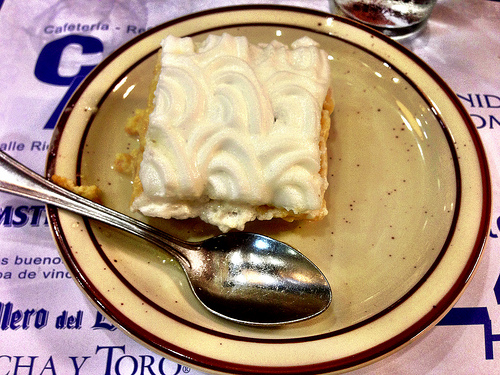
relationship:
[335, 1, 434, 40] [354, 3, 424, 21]
glass of water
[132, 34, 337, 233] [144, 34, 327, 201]
pie has frosting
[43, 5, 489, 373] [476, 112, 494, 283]
plate has rim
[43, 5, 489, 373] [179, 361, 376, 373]
plate has rim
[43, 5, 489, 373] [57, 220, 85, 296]
plate has rim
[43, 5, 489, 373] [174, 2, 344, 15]
plate has rim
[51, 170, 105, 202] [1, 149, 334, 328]
piece stuck under spoon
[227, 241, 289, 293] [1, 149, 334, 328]
light reflecting off of spoon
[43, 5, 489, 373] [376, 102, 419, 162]
plate has specks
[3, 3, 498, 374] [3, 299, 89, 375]
mat has writing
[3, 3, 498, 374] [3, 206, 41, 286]
mat has writing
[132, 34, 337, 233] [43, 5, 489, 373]
pie on plate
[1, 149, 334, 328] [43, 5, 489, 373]
spoon of plate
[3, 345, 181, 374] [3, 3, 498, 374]
writing on mat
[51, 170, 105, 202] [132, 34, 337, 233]
piece separated from pie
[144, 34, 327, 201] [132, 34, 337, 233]
frosting on top of pie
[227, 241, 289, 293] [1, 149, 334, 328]
light reflects off of spoon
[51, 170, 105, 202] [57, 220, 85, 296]
piece near rim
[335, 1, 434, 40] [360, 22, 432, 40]
glass has a base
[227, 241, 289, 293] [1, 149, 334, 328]
light reflected in spoon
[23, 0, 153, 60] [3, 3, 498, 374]
water ring on mat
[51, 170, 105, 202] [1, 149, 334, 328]
piece near spoon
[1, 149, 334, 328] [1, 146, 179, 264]
spoon has a handle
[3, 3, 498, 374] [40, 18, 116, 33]
mat has writing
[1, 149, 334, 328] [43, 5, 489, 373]
spoon on plate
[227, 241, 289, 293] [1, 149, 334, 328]
light reflecting in spoon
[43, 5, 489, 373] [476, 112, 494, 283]
plate has a rim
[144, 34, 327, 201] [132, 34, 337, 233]
frosting on pie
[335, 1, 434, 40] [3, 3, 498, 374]
glass on mat